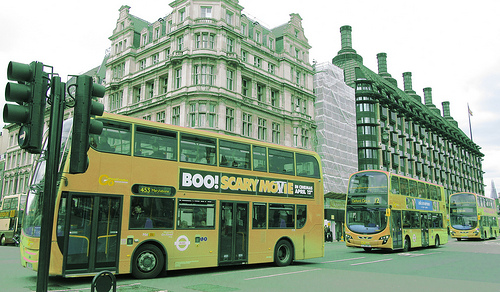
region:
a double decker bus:
[115, 139, 325, 272]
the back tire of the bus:
[276, 238, 293, 265]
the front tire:
[132, 245, 163, 275]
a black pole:
[40, 197, 50, 291]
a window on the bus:
[183, 142, 215, 163]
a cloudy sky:
[436, 49, 474, 78]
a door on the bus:
[216, 206, 246, 266]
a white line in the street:
[349, 252, 389, 268]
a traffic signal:
[7, 59, 32, 125]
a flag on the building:
[461, 104, 481, 133]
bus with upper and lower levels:
[21, 101, 337, 272]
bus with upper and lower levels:
[340, 170, 451, 247]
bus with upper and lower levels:
[448, 192, 498, 242]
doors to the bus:
[69, 200, 114, 264]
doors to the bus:
[222, 197, 243, 257]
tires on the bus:
[134, 230, 316, 282]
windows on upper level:
[105, 125, 296, 175]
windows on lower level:
[259, 204, 293, 227]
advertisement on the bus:
[179, 172, 319, 200]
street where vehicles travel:
[253, 262, 480, 289]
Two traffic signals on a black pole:
[1, 55, 108, 290]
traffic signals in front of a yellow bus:
[0, 52, 328, 289]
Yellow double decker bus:
[9, 105, 331, 285]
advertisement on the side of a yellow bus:
[168, 122, 328, 280]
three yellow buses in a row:
[13, 106, 499, 282]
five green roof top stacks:
[324, 20, 498, 153]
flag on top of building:
[456, 83, 487, 163]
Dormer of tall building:
[267, 5, 322, 100]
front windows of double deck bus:
[340, 158, 396, 266]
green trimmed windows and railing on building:
[226, 65, 301, 121]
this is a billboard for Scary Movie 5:
[175, 168, 320, 201]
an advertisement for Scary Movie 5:
[172, 162, 319, 202]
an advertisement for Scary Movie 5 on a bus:
[175, 157, 325, 204]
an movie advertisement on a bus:
[171, 157, 314, 200]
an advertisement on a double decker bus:
[170, 157, 321, 199]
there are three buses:
[25, 105, 498, 272]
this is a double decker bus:
[21, 106, 332, 278]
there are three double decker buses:
[38, 103, 498, 289]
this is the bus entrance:
[64, 188, 123, 272]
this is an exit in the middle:
[218, 198, 253, 265]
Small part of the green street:
[388, 263, 408, 283]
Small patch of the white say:
[365, 11, 402, 34]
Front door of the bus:
[66, 197, 117, 267]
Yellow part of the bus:
[108, 159, 120, 173]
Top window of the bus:
[105, 128, 130, 152]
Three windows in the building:
[241, 76, 283, 104]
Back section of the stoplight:
[77, 76, 87, 126]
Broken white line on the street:
[246, 265, 323, 283]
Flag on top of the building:
[463, 100, 476, 143]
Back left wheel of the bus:
[277, 242, 294, 267]